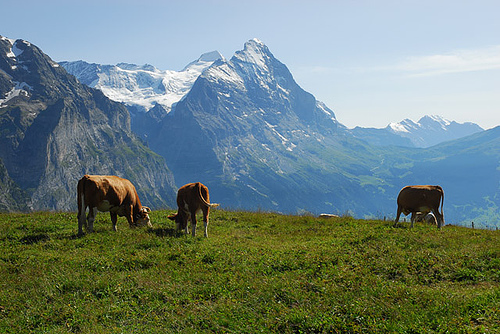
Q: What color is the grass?
A: Green.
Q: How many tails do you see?
A: 3.